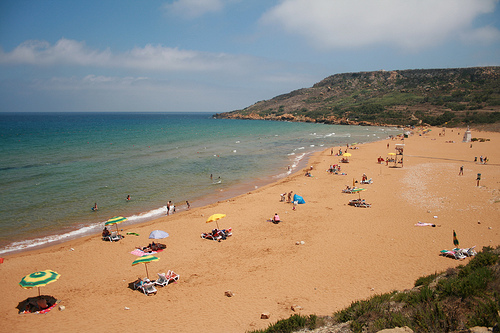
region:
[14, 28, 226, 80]
this is a cloud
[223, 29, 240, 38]
this is the blue sky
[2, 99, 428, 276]
this is an ocean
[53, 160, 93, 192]
this is the color blue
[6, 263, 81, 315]
this is an umbrella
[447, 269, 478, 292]
this is green vegetation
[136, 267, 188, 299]
these are white chairs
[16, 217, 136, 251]
this is a wave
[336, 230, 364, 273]
this is the sand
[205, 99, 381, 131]
this is the cliff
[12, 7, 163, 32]
the sky is blue and clear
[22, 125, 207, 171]
the ocean is blue and green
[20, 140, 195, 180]
the ocean is calm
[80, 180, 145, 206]
the people in the ocean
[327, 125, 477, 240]
the people on the beach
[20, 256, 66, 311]
the beach umbrella in the sand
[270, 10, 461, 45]
the cloud in the sky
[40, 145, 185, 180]
the waves in the ocean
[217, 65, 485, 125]
the hill beside the beach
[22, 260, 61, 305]
the yellow umbrella is open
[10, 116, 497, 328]
Sandy beach filled with people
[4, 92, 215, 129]
Blue horizon where the sea meets the sky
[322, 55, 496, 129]
Distant plateau against a cloudy blue sky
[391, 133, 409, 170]
Lifeguard tower in the sand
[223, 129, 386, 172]
Beach with small whitecap waves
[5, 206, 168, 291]
Three turquoise and yellow beach umbrellas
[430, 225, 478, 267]
Two lounge chairs with a closed beach umbrella inbetween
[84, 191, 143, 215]
Two people playing in the water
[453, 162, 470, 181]
A sole person walking in the sand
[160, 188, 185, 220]
A person watching over a toddler at the water's edge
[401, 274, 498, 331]
The hill is green.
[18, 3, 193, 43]
The sky is blue.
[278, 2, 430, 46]
The cloud is white.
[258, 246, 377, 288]
The ground is brown.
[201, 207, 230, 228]
Yellow umbrella on the beach.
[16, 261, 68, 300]
Green and yellow umbrella.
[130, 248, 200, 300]
People lounging under an umbrella.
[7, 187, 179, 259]
A line of white water.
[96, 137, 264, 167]
The water is grey.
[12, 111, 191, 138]
The water is blue.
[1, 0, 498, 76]
the sky s blue.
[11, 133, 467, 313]
people on the beach.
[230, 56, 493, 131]
cliffs behind the beach.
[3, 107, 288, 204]
the water is blu.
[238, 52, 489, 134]
green plants growing on the cliff.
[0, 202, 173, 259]
the waves are white.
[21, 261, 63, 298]
umbrella on the beach.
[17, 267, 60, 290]
yellow and green umbrella.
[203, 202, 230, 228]
one yellow umbrella.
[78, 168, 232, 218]
people in the water.